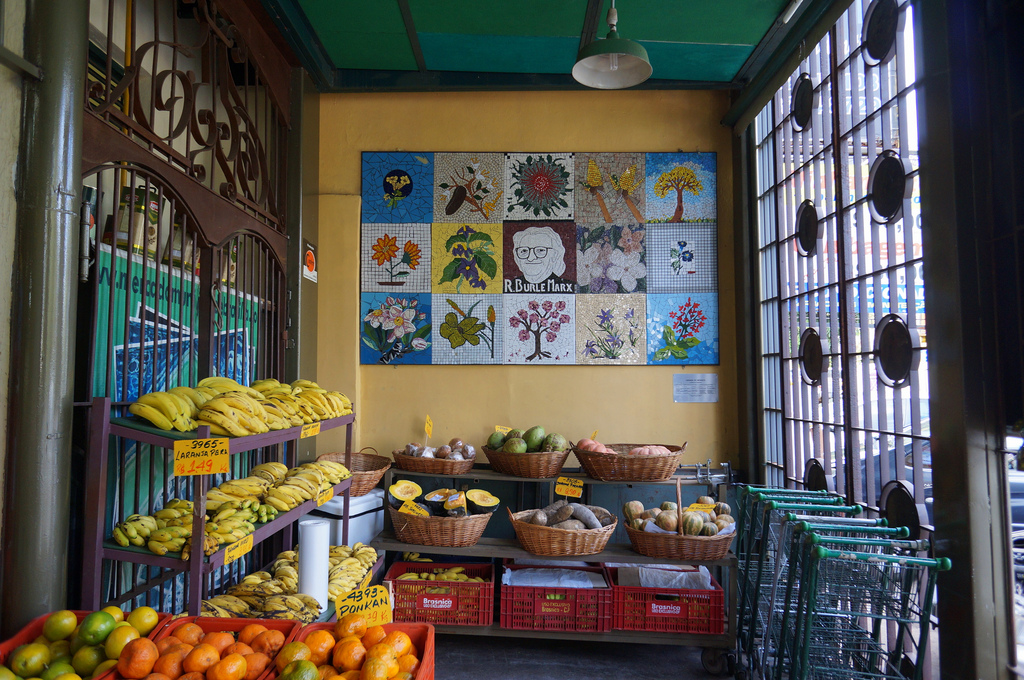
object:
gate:
[751, 0, 932, 529]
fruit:
[622, 496, 734, 537]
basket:
[622, 477, 735, 560]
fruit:
[515, 500, 613, 531]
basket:
[506, 504, 618, 556]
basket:
[388, 502, 494, 548]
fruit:
[388, 479, 501, 516]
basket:
[480, 441, 571, 479]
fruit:
[487, 425, 567, 453]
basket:
[392, 448, 475, 475]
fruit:
[405, 438, 476, 460]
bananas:
[129, 386, 206, 432]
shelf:
[109, 412, 356, 455]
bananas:
[242, 498, 279, 523]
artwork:
[361, 151, 722, 365]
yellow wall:
[299, 91, 740, 470]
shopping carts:
[710, 482, 953, 679]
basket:
[258, 622, 434, 678]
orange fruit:
[274, 614, 416, 680]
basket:
[99, 615, 299, 679]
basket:
[0, 609, 172, 680]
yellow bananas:
[129, 377, 353, 437]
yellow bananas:
[170, 542, 376, 627]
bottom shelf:
[198, 542, 382, 624]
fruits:
[121, 621, 283, 679]